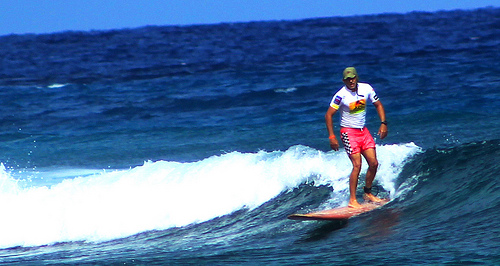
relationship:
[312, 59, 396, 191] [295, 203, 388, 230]
man on surboard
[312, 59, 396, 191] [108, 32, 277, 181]
man in water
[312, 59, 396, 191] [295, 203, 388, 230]
man using surboard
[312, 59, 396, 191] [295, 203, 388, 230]
man riding surboard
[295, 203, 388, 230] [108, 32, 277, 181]
surboard in water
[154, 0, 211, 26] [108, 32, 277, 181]
sky above water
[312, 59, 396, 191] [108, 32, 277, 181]
man riding water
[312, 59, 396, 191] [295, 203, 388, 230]
man in surboard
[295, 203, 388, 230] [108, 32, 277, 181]
surboard on water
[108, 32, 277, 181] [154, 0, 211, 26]
water below sky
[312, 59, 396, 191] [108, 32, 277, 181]
man near water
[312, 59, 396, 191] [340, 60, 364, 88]
man wearing cap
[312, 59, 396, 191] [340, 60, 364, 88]
man has cap